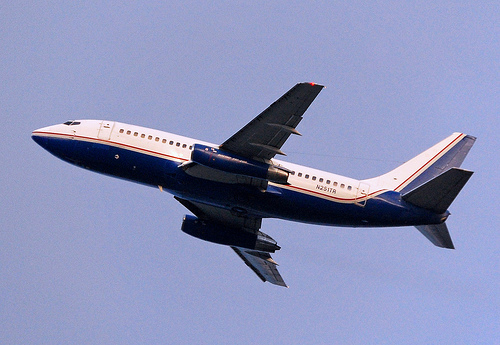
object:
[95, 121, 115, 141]
plane door